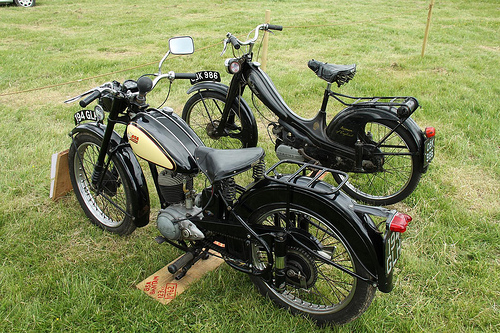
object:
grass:
[0, 0, 500, 333]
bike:
[64, 23, 434, 328]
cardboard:
[135, 239, 229, 305]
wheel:
[67, 132, 137, 237]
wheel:
[242, 203, 377, 327]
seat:
[194, 146, 265, 184]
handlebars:
[64, 71, 199, 108]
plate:
[385, 231, 400, 274]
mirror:
[169, 36, 195, 55]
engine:
[157, 169, 184, 202]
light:
[390, 212, 413, 233]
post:
[125, 121, 178, 172]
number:
[204, 72, 218, 79]